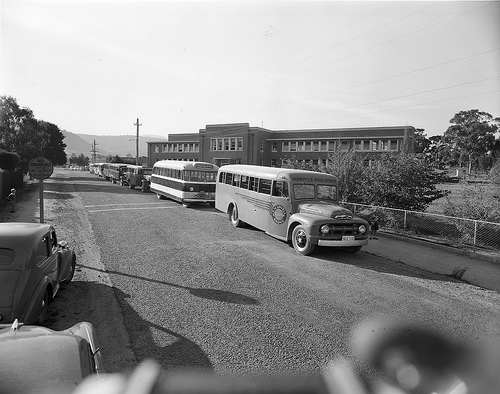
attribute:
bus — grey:
[215, 165, 371, 257]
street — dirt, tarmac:
[64, 167, 500, 393]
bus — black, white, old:
[151, 157, 219, 208]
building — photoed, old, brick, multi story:
[148, 122, 417, 180]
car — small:
[0, 219, 77, 328]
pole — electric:
[133, 117, 143, 157]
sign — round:
[28, 157, 56, 222]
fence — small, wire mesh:
[337, 201, 499, 253]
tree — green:
[20, 119, 66, 171]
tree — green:
[1, 152, 18, 194]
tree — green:
[1, 98, 34, 158]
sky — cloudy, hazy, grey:
[1, 3, 499, 149]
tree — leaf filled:
[441, 110, 498, 152]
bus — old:
[86, 165, 93, 173]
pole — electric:
[93, 139, 97, 159]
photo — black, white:
[1, 0, 499, 393]